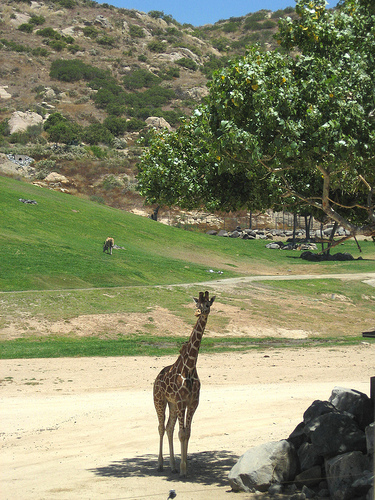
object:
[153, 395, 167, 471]
leg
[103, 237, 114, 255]
animal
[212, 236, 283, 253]
grass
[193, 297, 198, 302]
ear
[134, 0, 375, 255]
tree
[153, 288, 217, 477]
giraffe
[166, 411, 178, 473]
leg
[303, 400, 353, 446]
rock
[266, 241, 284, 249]
rock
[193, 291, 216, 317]
head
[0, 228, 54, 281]
grass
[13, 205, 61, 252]
grass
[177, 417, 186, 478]
giraffe's leg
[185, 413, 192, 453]
giraffe's leg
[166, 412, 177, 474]
giraffe's leg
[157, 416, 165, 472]
giraffe's leg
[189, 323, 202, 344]
neck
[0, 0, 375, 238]
hills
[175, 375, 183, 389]
brown spot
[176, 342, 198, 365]
neck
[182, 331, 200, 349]
neck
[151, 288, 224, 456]
giraffe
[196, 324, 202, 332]
brown spot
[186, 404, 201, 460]
leg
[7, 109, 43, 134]
rock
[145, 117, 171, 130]
rock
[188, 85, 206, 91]
rock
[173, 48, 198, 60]
rock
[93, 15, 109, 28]
rock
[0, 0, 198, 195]
hill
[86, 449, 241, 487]
shade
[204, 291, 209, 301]
horn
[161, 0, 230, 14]
sky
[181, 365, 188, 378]
brown spot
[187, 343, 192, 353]
spot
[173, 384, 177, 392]
brown spot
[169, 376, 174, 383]
brown spot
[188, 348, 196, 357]
brown spot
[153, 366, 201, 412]
body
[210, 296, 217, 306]
ear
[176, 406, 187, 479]
leg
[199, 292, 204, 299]
horn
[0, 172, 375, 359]
hill